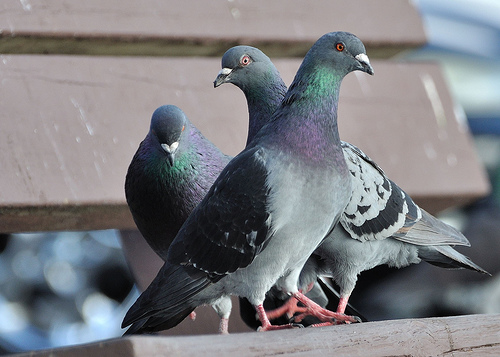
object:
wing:
[339, 140, 472, 247]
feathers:
[340, 140, 422, 243]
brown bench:
[1, 0, 500, 357]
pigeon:
[119, 30, 374, 338]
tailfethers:
[120, 260, 217, 337]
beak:
[350, 50, 375, 76]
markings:
[349, 160, 393, 227]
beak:
[213, 67, 234, 88]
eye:
[334, 40, 346, 53]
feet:
[254, 303, 305, 332]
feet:
[289, 284, 363, 324]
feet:
[289, 289, 362, 325]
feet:
[255, 285, 314, 321]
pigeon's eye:
[239, 53, 255, 68]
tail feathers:
[399, 191, 491, 278]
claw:
[288, 290, 362, 328]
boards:
[0, 54, 491, 235]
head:
[303, 30, 375, 76]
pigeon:
[124, 104, 368, 335]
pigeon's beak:
[159, 142, 180, 166]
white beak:
[219, 67, 233, 74]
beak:
[158, 142, 180, 166]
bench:
[0, 312, 499, 357]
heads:
[213, 45, 269, 88]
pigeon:
[212, 45, 492, 329]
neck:
[260, 76, 347, 152]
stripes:
[349, 149, 423, 236]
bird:
[120, 31, 374, 336]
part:
[313, 301, 320, 312]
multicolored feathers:
[282, 93, 337, 125]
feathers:
[167, 167, 351, 274]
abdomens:
[272, 160, 345, 268]